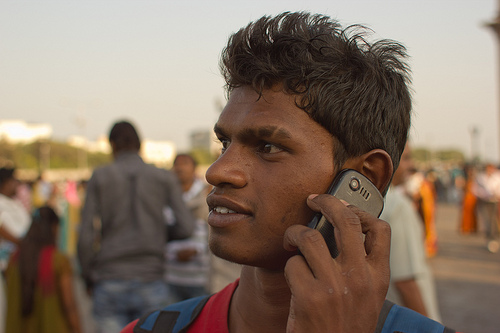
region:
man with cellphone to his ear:
[195, 7, 402, 272]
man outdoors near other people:
[27, 60, 474, 321]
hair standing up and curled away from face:
[212, 5, 427, 167]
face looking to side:
[190, 25, 387, 275]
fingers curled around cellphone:
[272, 181, 412, 306]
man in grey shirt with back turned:
[51, 105, 191, 310]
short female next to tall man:
[10, 105, 170, 320]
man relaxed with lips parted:
[195, 91, 295, 266]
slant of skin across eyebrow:
[240, 115, 300, 150]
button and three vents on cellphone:
[317, 153, 393, 235]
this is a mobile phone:
[321, 168, 391, 235]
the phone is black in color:
[329, 169, 379, 251]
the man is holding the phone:
[294, 172, 387, 332]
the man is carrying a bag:
[129, 282, 209, 332]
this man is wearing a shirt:
[84, 155, 194, 285]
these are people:
[0, 18, 492, 327]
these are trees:
[1, 134, 98, 165]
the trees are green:
[8, 138, 96, 163]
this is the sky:
[89, 10, 174, 107]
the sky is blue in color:
[44, 27, 179, 110]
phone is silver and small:
[308, 152, 394, 294]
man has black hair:
[178, 18, 432, 328]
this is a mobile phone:
[300, 164, 399, 281]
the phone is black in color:
[293, 165, 391, 276]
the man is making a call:
[185, 7, 422, 311]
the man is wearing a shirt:
[80, 158, 187, 300]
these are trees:
[2, 141, 84, 169]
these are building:
[5, 120, 214, 170]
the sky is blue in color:
[54, 5, 165, 84]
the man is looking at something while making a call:
[125, 13, 438, 326]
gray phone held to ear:
[307, 166, 392, 270]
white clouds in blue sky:
[61, 31, 78, 56]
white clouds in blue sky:
[144, 102, 159, 114]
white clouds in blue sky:
[58, 91, 73, 103]